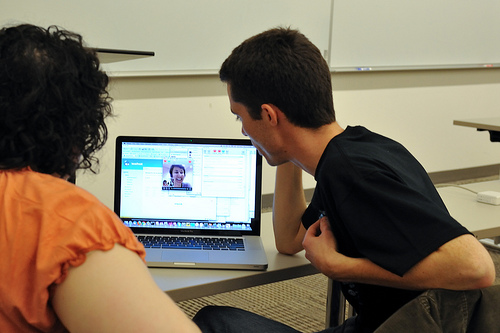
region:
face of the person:
[195, 32, 335, 152]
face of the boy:
[221, 45, 342, 165]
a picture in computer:
[149, 153, 208, 196]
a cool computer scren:
[101, 123, 321, 248]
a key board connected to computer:
[133, 225, 270, 250]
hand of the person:
[289, 210, 381, 280]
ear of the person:
[256, 99, 287, 130]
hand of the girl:
[41, 259, 191, 331]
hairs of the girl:
[0, 16, 112, 166]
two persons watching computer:
[22, 48, 492, 309]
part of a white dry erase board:
[1, 3, 498, 80]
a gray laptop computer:
[103, 132, 270, 269]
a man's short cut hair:
[215, 28, 340, 134]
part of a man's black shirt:
[297, 123, 469, 326]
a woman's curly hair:
[3, 22, 115, 188]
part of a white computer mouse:
[468, 184, 498, 207]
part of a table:
[115, 209, 346, 331]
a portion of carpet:
[218, 275, 352, 331]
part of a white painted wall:
[331, 74, 498, 170]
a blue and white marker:
[355, 65, 378, 72]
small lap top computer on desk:
[109, 138, 266, 273]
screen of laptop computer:
[102, 136, 262, 236]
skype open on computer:
[155, 154, 197, 189]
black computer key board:
[140, 234, 239, 253]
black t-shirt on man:
[304, 129, 465, 249]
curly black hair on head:
[0, 20, 103, 171]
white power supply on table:
[474, 188, 498, 210]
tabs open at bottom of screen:
[132, 220, 227, 228]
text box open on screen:
[207, 155, 241, 177]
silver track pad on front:
[155, 248, 204, 266]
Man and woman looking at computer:
[0, 21, 499, 331]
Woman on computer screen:
[163, 160, 195, 192]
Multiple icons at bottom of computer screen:
[123, 218, 253, 232]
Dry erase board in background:
[3, 2, 499, 69]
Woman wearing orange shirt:
[0, 169, 148, 331]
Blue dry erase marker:
[356, 63, 377, 70]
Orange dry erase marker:
[480, 63, 496, 70]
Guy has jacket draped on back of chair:
[376, 284, 498, 331]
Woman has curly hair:
[0, 23, 117, 183]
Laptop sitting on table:
[112, 135, 271, 269]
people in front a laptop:
[3, 4, 490, 324]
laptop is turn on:
[110, 127, 270, 282]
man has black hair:
[212, 23, 388, 210]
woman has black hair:
[0, 0, 140, 235]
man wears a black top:
[211, 20, 499, 325]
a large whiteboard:
[9, 2, 495, 87]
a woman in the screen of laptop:
[106, 129, 271, 240]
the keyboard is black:
[133, 220, 257, 257]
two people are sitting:
[1, 6, 481, 331]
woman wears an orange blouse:
[3, 23, 195, 328]